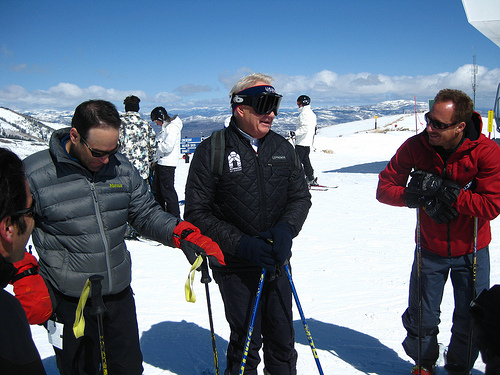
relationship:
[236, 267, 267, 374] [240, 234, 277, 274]
ski poles in hand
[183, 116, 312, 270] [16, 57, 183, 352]
coat on skier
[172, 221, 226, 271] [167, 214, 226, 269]
glove on hand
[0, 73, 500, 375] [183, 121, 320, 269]
man wearing coat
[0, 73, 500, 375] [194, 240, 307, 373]
man wearing pants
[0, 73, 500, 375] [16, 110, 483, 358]
man on slope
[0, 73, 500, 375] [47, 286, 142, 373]
man in pants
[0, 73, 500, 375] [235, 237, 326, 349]
man holding ski poles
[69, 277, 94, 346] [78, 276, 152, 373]
loop on poles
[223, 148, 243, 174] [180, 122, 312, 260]
logo on jacket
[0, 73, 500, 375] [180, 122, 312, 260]
man wears jacket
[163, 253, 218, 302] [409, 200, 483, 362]
wrist traps on ski poles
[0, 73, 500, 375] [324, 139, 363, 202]
man on slope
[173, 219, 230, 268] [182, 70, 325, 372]
glove on skier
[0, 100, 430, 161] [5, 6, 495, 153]
mountains in distance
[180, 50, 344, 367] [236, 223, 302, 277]
man in mittens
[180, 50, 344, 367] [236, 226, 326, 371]
man holding ski poles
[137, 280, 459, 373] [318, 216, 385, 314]
reflection in snow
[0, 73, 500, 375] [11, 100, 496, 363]
man on ski slope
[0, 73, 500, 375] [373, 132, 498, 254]
man wearing coat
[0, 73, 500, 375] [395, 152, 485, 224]
man wearing gloves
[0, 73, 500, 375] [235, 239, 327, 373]
man holding ski poles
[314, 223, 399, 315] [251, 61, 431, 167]
snow on mountain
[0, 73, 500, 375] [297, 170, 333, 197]
man on skis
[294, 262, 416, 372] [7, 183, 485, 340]
shadow being cast on ground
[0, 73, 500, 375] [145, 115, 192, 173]
man wearing coats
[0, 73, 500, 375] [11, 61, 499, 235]
man in background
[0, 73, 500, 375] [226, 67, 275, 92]
man with hair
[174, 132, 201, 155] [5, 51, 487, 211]
sign in background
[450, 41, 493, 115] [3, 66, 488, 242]
tree in background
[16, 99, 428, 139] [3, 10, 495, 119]
mountains in distance